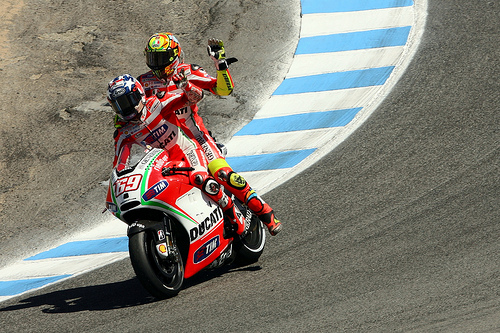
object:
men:
[133, 33, 286, 236]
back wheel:
[230, 190, 273, 263]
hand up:
[214, 87, 241, 103]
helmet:
[107, 73, 147, 124]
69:
[115, 174, 140, 197]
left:
[91, 175, 134, 291]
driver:
[104, 73, 254, 242]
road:
[7, 10, 496, 333]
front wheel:
[126, 216, 185, 297]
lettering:
[188, 205, 223, 242]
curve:
[203, 0, 442, 181]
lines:
[293, 23, 412, 59]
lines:
[290, 44, 406, 77]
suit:
[108, 90, 249, 240]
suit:
[131, 65, 273, 230]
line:
[0, 274, 81, 303]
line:
[24, 234, 135, 265]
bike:
[104, 146, 267, 299]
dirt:
[4, 3, 482, 322]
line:
[268, 61, 397, 98]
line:
[226, 147, 317, 171]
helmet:
[144, 30, 182, 78]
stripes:
[0, 9, 429, 300]